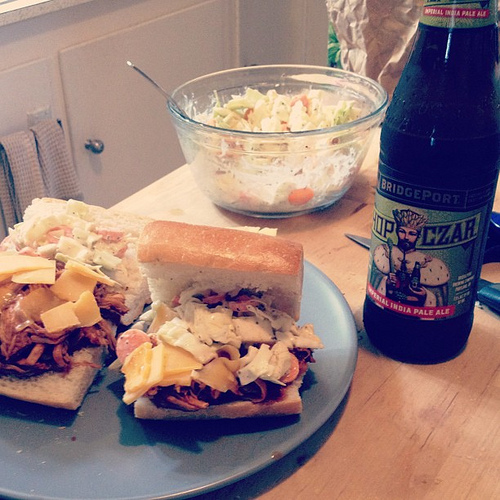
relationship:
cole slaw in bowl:
[199, 90, 360, 189] [133, 49, 359, 199]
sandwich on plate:
[125, 219, 302, 423] [0, 254, 361, 499]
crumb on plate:
[36, 429, 86, 447] [2, 180, 367, 490]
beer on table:
[355, 66, 478, 314] [3, 47, 485, 484]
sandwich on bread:
[125, 219, 302, 423] [143, 219, 303, 289]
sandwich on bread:
[3, 182, 160, 417] [34, 379, 74, 404]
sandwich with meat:
[125, 219, 302, 423] [154, 390, 208, 412]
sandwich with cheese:
[125, 219, 302, 423] [125, 343, 162, 388]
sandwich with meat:
[3, 182, 160, 417] [12, 341, 68, 369]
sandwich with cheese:
[3, 182, 160, 417] [1, 255, 55, 281]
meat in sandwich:
[17, 322, 67, 369] [17, 210, 101, 398]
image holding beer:
[372, 208, 449, 321] [405, 247, 424, 300]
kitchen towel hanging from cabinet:
[29, 119, 84, 204] [0, 2, 336, 254]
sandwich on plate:
[3, 182, 160, 417] [0, 254, 361, 499]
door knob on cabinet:
[86, 137, 107, 155] [1, 3, 240, 199]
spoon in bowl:
[125, 60, 193, 122] [167, 61, 387, 220]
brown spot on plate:
[263, 450, 280, 462] [2, 219, 362, 499]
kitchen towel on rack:
[10, 118, 85, 220] [0, 118, 68, 178]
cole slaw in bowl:
[199, 90, 360, 189] [161, 55, 393, 223]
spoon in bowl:
[122, 54, 192, 122] [161, 55, 393, 223]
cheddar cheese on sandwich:
[120, 343, 201, 406] [125, 219, 302, 423]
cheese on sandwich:
[0, 252, 101, 343] [3, 182, 160, 417]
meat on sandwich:
[145, 348, 315, 417] [109, 180, 339, 444]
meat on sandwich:
[0, 283, 132, 377] [3, 182, 160, 417]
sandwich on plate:
[125, 219, 302, 423] [2, 180, 367, 490]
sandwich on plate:
[3, 182, 160, 417] [2, 180, 367, 490]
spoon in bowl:
[122, 54, 192, 122] [167, 61, 387, 220]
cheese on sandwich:
[0, 252, 101, 343] [0, 194, 153, 416]